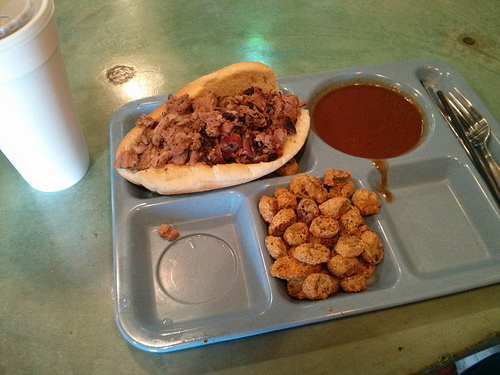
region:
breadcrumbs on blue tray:
[233, 168, 386, 298]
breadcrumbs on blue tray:
[247, 197, 335, 275]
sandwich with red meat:
[126, 93, 333, 172]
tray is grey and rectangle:
[76, 63, 493, 237]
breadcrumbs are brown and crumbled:
[246, 164, 408, 311]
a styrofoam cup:
[0, 2, 108, 192]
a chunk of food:
[272, 252, 299, 279]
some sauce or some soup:
[306, 82, 428, 161]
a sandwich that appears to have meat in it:
[117, 71, 346, 180]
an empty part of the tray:
[150, 222, 262, 317]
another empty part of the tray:
[354, 165, 498, 281]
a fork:
[449, 78, 499, 188]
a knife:
[414, 65, 498, 215]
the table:
[0, 2, 492, 368]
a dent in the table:
[102, 55, 148, 87]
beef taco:
[115, 59, 295, 171]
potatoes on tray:
[247, 174, 379, 309]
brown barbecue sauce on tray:
[310, 60, 430, 167]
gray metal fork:
[439, 79, 498, 199]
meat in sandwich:
[129, 95, 291, 165]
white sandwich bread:
[109, 61, 311, 196]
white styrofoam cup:
[2, 3, 92, 201]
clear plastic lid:
[0, 1, 53, 45]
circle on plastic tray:
[154, 228, 242, 309]